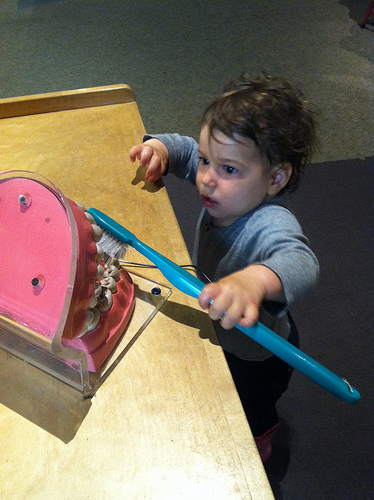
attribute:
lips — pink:
[199, 190, 220, 207]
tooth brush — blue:
[83, 206, 360, 402]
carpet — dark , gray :
[270, 157, 373, 479]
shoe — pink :
[244, 406, 309, 475]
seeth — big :
[58, 238, 156, 358]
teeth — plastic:
[0, 167, 139, 374]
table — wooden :
[1, 81, 277, 498]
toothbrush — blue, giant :
[98, 203, 369, 409]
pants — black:
[224, 311, 299, 436]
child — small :
[119, 94, 310, 346]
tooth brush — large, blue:
[79, 199, 370, 418]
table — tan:
[3, 79, 215, 315]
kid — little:
[145, 49, 326, 249]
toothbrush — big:
[73, 204, 251, 286]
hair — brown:
[200, 74, 319, 192]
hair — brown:
[199, 62, 324, 200]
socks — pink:
[253, 425, 276, 473]